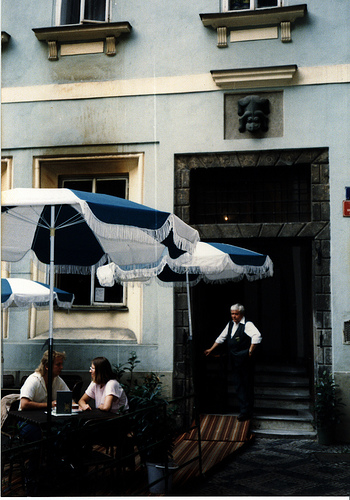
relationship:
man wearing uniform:
[215, 301, 260, 421] [226, 329, 249, 394]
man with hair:
[215, 301, 260, 421] [233, 305, 247, 310]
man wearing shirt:
[215, 301, 260, 421] [250, 327, 255, 338]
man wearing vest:
[215, 301, 260, 421] [230, 336, 245, 348]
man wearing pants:
[215, 301, 260, 421] [239, 367, 256, 416]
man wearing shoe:
[215, 301, 260, 421] [236, 413, 250, 425]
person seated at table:
[89, 357, 123, 410] [30, 407, 49, 423]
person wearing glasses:
[89, 357, 123, 410] [91, 366, 96, 372]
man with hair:
[22, 354, 53, 410] [41, 356, 47, 374]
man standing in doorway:
[215, 301, 260, 421] [207, 284, 291, 298]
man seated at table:
[22, 354, 53, 410] [30, 407, 49, 423]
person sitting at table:
[89, 357, 123, 410] [30, 407, 49, 423]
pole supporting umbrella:
[50, 241, 56, 407] [6, 196, 195, 271]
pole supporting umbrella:
[185, 273, 196, 344] [106, 247, 266, 287]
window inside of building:
[38, 160, 140, 193] [0, 7, 347, 158]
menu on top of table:
[55, 391, 73, 415] [30, 407, 49, 423]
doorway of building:
[207, 284, 291, 298] [0, 7, 347, 158]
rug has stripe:
[177, 416, 241, 468] [227, 418, 233, 441]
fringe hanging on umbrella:
[55, 266, 91, 277] [6, 196, 195, 271]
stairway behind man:
[257, 365, 303, 416] [215, 301, 260, 421]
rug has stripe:
[177, 416, 241, 468] [181, 441, 191, 460]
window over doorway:
[194, 175, 306, 221] [207, 284, 291, 298]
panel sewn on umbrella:
[195, 246, 221, 267] [106, 247, 266, 287]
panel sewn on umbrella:
[85, 204, 155, 225] [6, 196, 195, 271]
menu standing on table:
[55, 391, 73, 415] [30, 407, 49, 423]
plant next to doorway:
[317, 375, 341, 427] [207, 284, 291, 298]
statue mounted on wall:
[237, 92, 276, 138] [184, 97, 217, 139]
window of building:
[47, 3, 113, 24] [0, 7, 347, 158]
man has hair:
[22, 354, 53, 410] [41, 356, 47, 374]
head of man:
[230, 310, 242, 321] [215, 301, 260, 421]